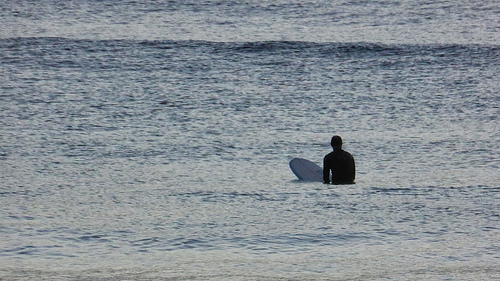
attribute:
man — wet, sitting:
[329, 133, 356, 196]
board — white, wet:
[289, 149, 323, 181]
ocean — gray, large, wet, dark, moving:
[114, 109, 171, 143]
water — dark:
[235, 81, 266, 109]